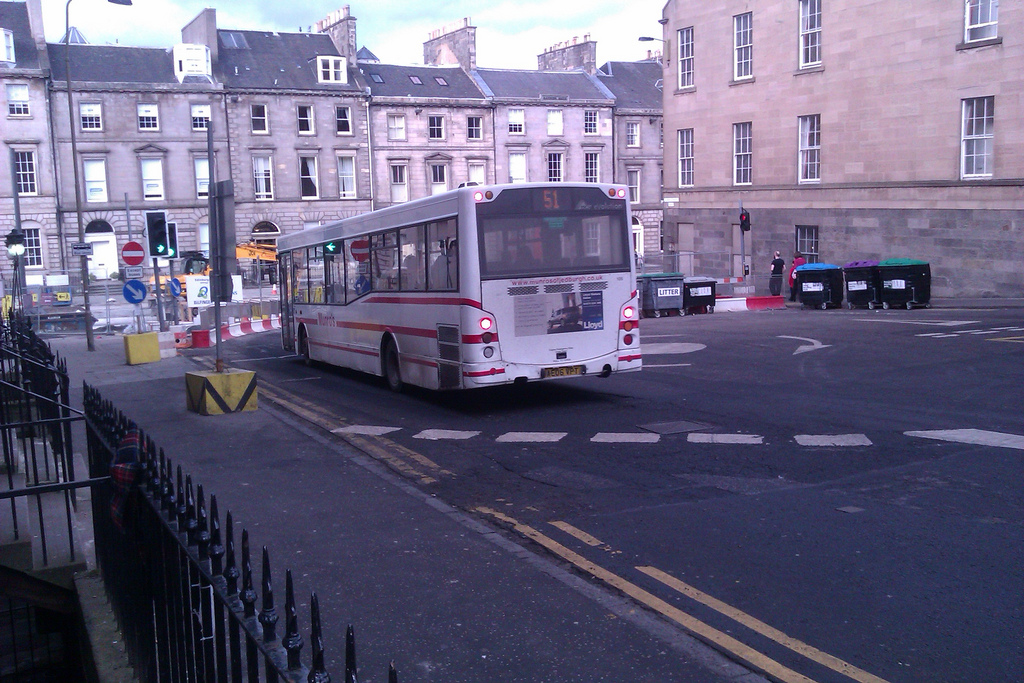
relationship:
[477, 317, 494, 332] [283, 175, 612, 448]
light belongs to bus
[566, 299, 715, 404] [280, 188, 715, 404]
headlight belongs to bus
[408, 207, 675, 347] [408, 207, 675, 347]
window belongs to bus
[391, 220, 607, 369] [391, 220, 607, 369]
window belongs to bus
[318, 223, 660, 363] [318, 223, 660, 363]
window belongs to bus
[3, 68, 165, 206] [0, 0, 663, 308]
window on building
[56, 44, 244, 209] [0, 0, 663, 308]
window on building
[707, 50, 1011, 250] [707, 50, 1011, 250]
window on building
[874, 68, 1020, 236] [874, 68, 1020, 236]
window on building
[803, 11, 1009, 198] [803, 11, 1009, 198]
window on building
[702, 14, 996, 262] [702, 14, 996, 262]
window on building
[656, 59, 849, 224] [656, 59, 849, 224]
window on building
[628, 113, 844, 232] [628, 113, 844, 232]
window on building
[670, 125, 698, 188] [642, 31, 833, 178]
window on building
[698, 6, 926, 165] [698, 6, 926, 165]
window on building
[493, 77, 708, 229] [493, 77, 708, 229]
window on building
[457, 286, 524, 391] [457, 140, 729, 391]
light on back of bus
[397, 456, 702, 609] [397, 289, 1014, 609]
lines on street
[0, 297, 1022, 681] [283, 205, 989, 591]
street behind bus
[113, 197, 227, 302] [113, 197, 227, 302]
light on pole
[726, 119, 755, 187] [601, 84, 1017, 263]
window on building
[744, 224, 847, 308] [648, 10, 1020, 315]
people next to building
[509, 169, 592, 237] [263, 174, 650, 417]
number on back of bus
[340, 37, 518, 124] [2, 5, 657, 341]
roof on building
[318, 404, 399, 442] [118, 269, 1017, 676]
square on street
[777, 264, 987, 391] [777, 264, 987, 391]
trashcans next to street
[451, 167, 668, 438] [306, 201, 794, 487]
back of bus